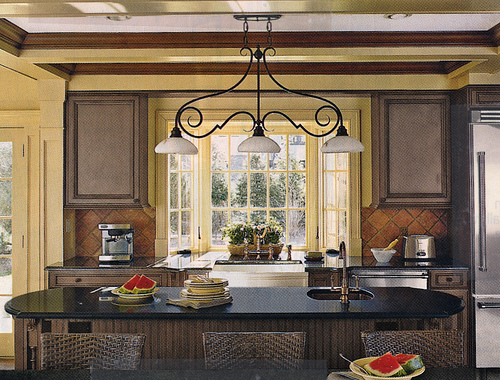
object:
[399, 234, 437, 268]
toaster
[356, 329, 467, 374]
chairs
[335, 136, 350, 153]
light bulb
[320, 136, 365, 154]
light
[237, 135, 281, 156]
light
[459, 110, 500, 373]
fridge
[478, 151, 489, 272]
handle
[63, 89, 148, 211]
wooden shelf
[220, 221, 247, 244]
plant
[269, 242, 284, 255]
pots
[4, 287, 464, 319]
counter top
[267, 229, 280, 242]
plants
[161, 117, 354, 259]
window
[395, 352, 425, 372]
watermelon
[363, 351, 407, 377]
watermelon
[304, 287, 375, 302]
sink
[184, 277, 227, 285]
plates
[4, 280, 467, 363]
counter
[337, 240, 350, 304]
faucet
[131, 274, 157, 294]
watermelon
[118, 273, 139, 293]
watermelon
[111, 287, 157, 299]
plate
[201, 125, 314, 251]
frame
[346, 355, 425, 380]
bowl